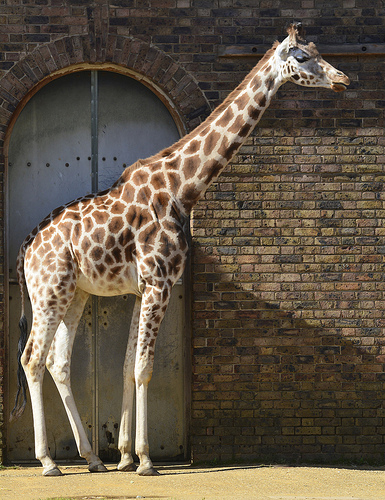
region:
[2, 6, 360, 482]
A giraffe in front of a building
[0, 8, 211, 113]
A brick archway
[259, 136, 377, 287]
A brick wall in sunlight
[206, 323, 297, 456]
Brick wall in shadow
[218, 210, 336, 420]
A brick wall partially shaded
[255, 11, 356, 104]
Head of a giraffe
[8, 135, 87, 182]
Rivets of a metal door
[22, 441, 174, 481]
Hoofs of a giraffe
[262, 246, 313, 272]
A dark brick surrounded by lighter ones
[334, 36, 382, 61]
A piece of wood against a brick wall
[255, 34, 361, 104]
face of the giraffe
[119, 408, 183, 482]
front legs of the giraffe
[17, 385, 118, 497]
back legs of the giraffe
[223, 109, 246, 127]
skin of the giraffe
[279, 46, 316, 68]
eye of the giraffe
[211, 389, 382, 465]
a group of bricks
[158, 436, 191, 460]
a small mark on wall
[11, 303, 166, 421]
sun shine falling on legs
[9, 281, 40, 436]
tail of the giraffe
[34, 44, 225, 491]
a big strong gate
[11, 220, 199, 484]
four white legs of giraffe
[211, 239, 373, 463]
wall of red and brown bricks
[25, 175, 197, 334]
brown spots of giraffe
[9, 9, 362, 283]
giraffe standing in front of brick wall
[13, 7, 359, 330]
giraffe with spots and long neck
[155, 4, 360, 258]
long spotted neck of giraffe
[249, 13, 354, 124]
spotted head of giraffe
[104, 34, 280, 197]
short mane on back of giraffe's neck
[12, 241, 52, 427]
black hair at end of giraffe's tail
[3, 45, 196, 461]
two arched metal doors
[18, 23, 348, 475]
brown and white giraffe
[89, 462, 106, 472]
tan hoof on giraffe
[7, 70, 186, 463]
rusted metal door in wall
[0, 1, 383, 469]
brown stacked brick building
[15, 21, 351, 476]
giraffe standing by wall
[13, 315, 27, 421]
black tail of giraffe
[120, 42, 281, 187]
brown mane of giraffe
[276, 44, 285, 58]
white ear of giraffe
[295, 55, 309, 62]
brown eye on giraffe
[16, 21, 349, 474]
giraffe standing on ground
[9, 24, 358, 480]
The giraffe is very big.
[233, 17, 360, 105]
The giraffe has his eyes closed.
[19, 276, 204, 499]
The giraffe has long legs.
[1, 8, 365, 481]
The giraffe is standing next to the building.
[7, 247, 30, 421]
The giraffe has a long tail.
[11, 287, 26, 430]
The giraffe's tail is black.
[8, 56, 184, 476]
The steel door is behind the giraffe.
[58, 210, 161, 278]
The giraffe has brown spots.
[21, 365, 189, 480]
The giraffe has white legs.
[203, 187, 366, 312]
The wall behind the giraffe is brick.